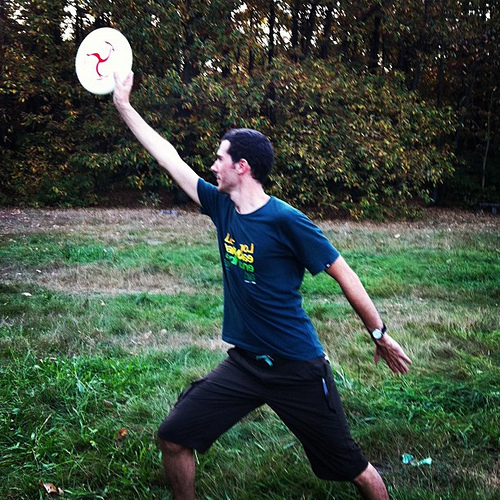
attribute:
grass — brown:
[4, 208, 214, 237]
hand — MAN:
[107, 69, 137, 112]